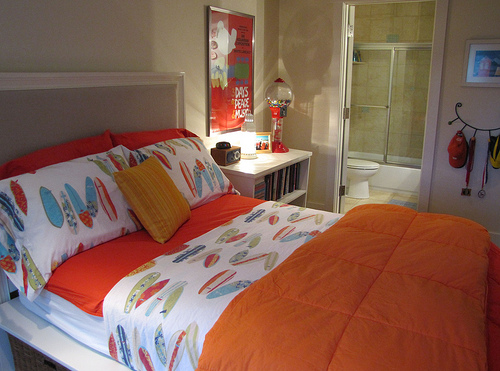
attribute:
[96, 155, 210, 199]
pillows — white, yellow, four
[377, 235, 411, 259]
comforter — orange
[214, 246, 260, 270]
sheets — patterned, orange, red, surfboard, white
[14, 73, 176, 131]
board — grey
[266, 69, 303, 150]
machine — red, small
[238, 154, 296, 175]
shelves — white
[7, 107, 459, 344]
bed — made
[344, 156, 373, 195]
toilet — white, closed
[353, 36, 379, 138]
door — glass, open, framed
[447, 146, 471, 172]
hat — red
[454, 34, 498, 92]
picture — framed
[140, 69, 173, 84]
headboard — white